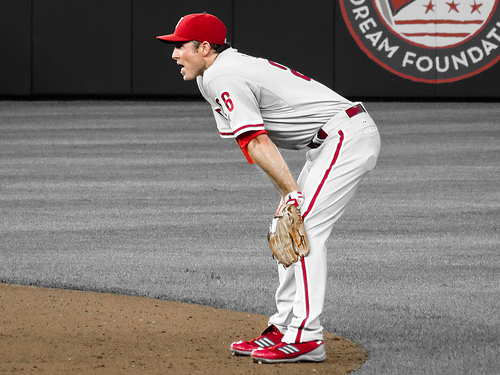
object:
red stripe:
[296, 130, 344, 221]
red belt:
[344, 106, 364, 118]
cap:
[155, 11, 229, 48]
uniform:
[189, 47, 383, 343]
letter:
[398, 49, 416, 69]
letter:
[415, 56, 434, 74]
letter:
[435, 56, 449, 72]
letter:
[464, 44, 485, 64]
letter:
[376, 37, 400, 59]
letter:
[365, 31, 381, 47]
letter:
[357, 16, 377, 34]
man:
[154, 9, 383, 363]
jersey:
[193, 44, 358, 151]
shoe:
[250, 333, 329, 365]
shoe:
[229, 325, 285, 357]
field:
[2, 98, 498, 372]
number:
[221, 90, 237, 111]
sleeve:
[209, 77, 266, 134]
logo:
[333, 0, 499, 83]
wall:
[7, 1, 128, 99]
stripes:
[220, 122, 267, 142]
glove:
[266, 190, 310, 267]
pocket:
[351, 113, 377, 141]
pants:
[266, 101, 383, 345]